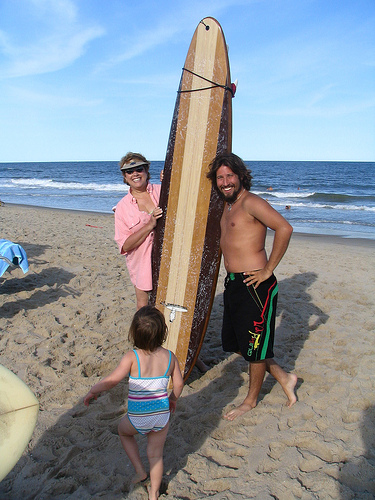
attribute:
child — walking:
[49, 293, 227, 500]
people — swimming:
[253, 167, 347, 221]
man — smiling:
[187, 111, 316, 399]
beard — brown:
[223, 177, 249, 205]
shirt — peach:
[93, 185, 184, 328]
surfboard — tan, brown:
[162, 19, 252, 161]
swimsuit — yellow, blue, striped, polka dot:
[199, 274, 280, 350]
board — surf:
[166, 19, 272, 106]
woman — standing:
[70, 115, 191, 322]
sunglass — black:
[103, 150, 155, 186]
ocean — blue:
[27, 147, 128, 198]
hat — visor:
[110, 140, 154, 177]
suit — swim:
[88, 342, 213, 443]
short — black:
[198, 267, 304, 357]